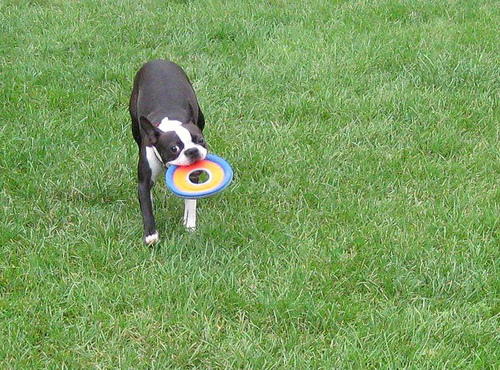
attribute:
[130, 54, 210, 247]
dog — black and white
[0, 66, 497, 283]
grass — green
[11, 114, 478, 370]
grass — green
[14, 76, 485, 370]
grass — green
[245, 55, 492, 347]
grass — green